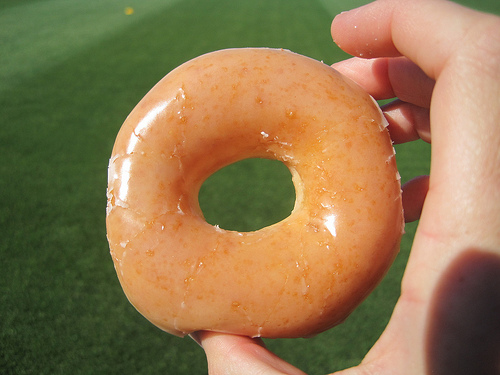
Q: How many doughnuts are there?
A: One.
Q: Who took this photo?
A: The person holding the doughnut.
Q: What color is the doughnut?
A: Brown.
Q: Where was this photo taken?
A: Outside on the lawn.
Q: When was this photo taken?
A: During the day.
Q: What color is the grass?
A: Green.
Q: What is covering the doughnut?
A: Glaze.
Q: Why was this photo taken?
A: To show the doughnut.